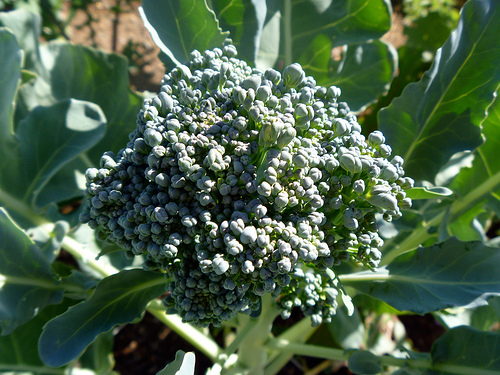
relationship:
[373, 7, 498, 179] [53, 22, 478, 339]
leaf on brocooli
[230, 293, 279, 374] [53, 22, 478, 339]
stalk on brocooli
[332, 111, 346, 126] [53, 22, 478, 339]
seedling on brocooli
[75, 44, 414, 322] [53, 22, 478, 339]
head of brocooli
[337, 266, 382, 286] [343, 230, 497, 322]
stem of leaf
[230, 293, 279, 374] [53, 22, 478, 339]
stalk of brocooli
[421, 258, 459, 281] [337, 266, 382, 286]
branch on stem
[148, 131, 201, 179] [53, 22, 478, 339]
florets on brocooli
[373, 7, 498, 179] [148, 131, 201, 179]
leaf on top of florets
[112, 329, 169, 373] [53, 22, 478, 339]
dirt behind brocooli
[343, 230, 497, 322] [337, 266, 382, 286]
leaf has stem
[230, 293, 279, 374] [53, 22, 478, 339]
stalk attached to brocooli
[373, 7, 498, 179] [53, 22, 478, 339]
leaf attached to brocooli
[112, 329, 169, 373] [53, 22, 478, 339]
dirt under brocooli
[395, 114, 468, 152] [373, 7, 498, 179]
vein in leaf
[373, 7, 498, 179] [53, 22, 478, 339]
leaf behind brocooli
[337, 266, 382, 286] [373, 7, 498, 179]
stem attached leaf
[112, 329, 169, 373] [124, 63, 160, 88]
dirt has shadow